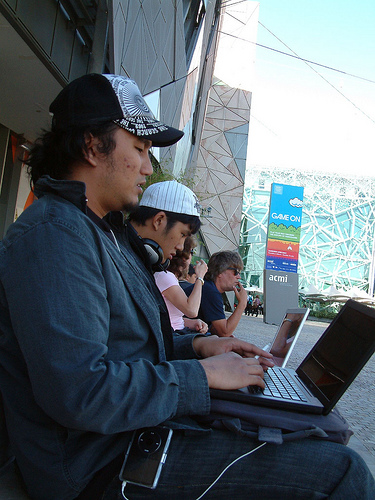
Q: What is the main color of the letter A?
A: White.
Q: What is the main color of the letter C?
A: White.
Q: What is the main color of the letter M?
A: White.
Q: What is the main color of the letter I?
A: White.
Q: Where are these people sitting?
A: Outside of a building.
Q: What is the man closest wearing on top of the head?
A: Hat.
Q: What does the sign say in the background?
A: GAME ON.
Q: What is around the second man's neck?
A: Headphones.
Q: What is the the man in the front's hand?
A: Cigarette.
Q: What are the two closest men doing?
A: On their laptops.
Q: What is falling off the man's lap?
A: MP3 player.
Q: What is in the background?
A: Building.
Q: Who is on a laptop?
A: Two men at the front.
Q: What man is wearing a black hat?
A: The man with blue jeans.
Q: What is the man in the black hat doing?
A: Using a laptop.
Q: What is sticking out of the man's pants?
A: An iPod.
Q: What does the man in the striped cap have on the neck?
A: Headphones.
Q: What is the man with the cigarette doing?
A: Typing on a laptop.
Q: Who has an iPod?
A: Man with the black cap.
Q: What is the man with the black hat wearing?
A: A blue jacket.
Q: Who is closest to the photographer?
A: A man in a black cap.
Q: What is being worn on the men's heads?
A: Hats.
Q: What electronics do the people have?
A: Laptops.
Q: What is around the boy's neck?
A: Headphones.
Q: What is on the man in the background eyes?
A: Sunglasses.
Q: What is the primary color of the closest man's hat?
A: Balck.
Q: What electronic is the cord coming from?
A: Ipod.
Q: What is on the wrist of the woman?
A: Watch.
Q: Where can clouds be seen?
A: Sign.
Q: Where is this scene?
A: Stoop.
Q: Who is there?
A: 4 people.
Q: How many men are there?
A: 3.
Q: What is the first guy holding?
A: Laptop.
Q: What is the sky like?
A: Overcast.